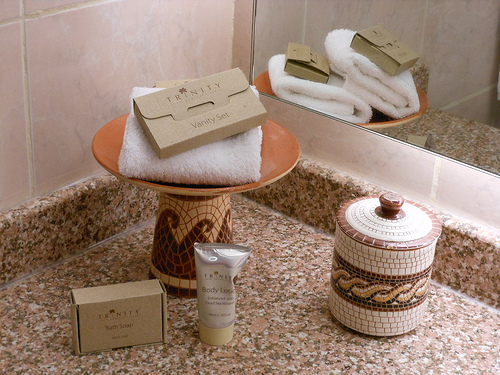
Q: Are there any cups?
A: No, there are no cups.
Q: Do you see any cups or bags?
A: No, there are no cups or bags.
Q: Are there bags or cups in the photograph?
A: No, there are no cups or bags.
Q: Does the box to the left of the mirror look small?
A: Yes, the box is small.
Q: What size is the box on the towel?
A: The box is small.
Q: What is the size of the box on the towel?
A: The box is small.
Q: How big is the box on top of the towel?
A: The box is small.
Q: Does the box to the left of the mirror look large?
A: No, the box is small.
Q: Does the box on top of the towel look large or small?
A: The box is small.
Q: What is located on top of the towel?
A: The box is on top of the towel.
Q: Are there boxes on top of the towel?
A: Yes, there is a box on top of the towel.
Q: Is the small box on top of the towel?
A: Yes, the box is on top of the towel.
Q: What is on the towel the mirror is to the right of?
A: The box is on the towel.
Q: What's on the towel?
A: The box is on the towel.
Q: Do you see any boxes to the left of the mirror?
A: Yes, there is a box to the left of the mirror.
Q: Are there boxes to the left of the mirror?
A: Yes, there is a box to the left of the mirror.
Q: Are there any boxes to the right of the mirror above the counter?
A: No, the box is to the left of the mirror.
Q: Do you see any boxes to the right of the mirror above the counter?
A: No, the box is to the left of the mirror.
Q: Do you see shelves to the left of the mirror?
A: No, there is a box to the left of the mirror.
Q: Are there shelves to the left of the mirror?
A: No, there is a box to the left of the mirror.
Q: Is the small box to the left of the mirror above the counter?
A: Yes, the box is to the left of the mirror.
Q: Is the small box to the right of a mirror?
A: No, the box is to the left of a mirror.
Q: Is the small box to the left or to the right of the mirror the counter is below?
A: The box is to the left of the mirror.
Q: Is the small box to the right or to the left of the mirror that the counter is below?
A: The box is to the left of the mirror.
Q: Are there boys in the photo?
A: No, there are no boys.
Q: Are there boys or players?
A: No, there are no boys or players.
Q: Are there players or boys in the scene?
A: No, there are no boys or players.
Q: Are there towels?
A: Yes, there is a towel.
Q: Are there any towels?
A: Yes, there is a towel.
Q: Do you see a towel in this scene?
A: Yes, there is a towel.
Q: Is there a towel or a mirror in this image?
A: Yes, there is a towel.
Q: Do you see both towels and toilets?
A: No, there is a towel but no toilets.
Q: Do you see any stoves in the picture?
A: No, there are no stoves.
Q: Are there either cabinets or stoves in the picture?
A: No, there are no stoves or cabinets.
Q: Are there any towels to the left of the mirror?
A: Yes, there is a towel to the left of the mirror.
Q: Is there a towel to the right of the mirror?
A: No, the towel is to the left of the mirror.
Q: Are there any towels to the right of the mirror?
A: No, the towel is to the left of the mirror.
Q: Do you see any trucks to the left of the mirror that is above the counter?
A: No, there is a towel to the left of the mirror.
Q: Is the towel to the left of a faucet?
A: No, the towel is to the left of the mirror.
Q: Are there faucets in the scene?
A: No, there are no faucets.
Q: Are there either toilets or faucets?
A: No, there are no faucets or toilets.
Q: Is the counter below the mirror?
A: Yes, the counter is below the mirror.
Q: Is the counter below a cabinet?
A: No, the counter is below the mirror.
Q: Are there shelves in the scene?
A: No, there are no shelves.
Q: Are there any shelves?
A: No, there are no shelves.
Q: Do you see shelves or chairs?
A: No, there are no shelves or chairs.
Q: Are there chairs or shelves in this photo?
A: No, there are no shelves or chairs.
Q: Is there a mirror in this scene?
A: Yes, there is a mirror.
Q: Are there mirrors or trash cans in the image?
A: Yes, there is a mirror.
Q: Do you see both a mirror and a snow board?
A: No, there is a mirror but no snowboards.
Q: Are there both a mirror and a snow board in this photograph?
A: No, there is a mirror but no snowboards.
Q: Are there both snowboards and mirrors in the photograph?
A: No, there is a mirror but no snowboards.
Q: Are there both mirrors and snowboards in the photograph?
A: No, there is a mirror but no snowboards.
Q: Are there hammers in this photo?
A: No, there are no hammers.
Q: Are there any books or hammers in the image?
A: No, there are no hammers or books.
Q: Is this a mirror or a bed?
A: This is a mirror.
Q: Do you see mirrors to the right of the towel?
A: Yes, there is a mirror to the right of the towel.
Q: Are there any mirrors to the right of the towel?
A: Yes, there is a mirror to the right of the towel.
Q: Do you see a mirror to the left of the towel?
A: No, the mirror is to the right of the towel.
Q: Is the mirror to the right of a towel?
A: Yes, the mirror is to the right of a towel.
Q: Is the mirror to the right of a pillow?
A: No, the mirror is to the right of a towel.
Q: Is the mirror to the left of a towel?
A: No, the mirror is to the right of a towel.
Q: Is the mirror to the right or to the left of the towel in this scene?
A: The mirror is to the right of the towel.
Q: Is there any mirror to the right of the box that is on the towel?
A: Yes, there is a mirror to the right of the box.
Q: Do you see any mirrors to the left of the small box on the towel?
A: No, the mirror is to the right of the box.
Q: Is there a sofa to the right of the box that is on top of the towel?
A: No, there is a mirror to the right of the box.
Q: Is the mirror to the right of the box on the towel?
A: Yes, the mirror is to the right of the box.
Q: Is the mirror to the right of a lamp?
A: No, the mirror is to the right of the box.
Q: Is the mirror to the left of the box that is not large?
A: No, the mirror is to the right of the box.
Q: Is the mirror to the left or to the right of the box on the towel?
A: The mirror is to the right of the box.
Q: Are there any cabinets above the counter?
A: No, there is a mirror above the counter.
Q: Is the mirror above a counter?
A: Yes, the mirror is above a counter.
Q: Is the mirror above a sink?
A: No, the mirror is above a counter.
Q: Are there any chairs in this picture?
A: No, there are no chairs.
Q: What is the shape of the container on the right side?
A: The container is round.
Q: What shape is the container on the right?
A: The container is round.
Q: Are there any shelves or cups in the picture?
A: No, there are no cups or shelves.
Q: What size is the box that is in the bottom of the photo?
A: The box is little.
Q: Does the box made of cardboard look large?
A: No, the box is little.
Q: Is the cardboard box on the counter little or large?
A: The box is little.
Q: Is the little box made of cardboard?
A: Yes, the box is made of cardboard.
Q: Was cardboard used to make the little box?
A: Yes, the box is made of cardboard.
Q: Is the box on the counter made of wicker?
A: No, the box is made of cardboard.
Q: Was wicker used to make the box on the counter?
A: No, the box is made of cardboard.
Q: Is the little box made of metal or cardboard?
A: The box is made of cardboard.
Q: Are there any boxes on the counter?
A: Yes, there is a box on the counter.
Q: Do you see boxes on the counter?
A: Yes, there is a box on the counter.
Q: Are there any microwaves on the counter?
A: No, there is a box on the counter.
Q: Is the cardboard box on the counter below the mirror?
A: Yes, the box is on the counter.